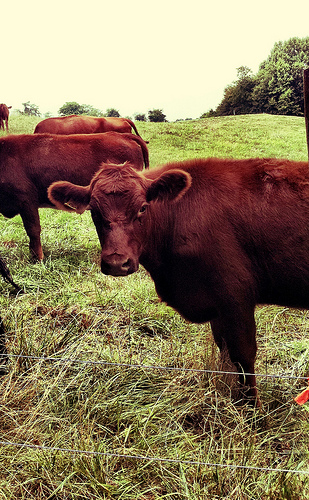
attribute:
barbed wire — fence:
[84, 357, 237, 384]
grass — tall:
[1, 110, 306, 496]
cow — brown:
[57, 150, 308, 400]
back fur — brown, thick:
[167, 156, 302, 168]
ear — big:
[45, 179, 92, 214]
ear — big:
[147, 168, 192, 203]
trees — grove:
[174, 26, 308, 140]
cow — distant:
[45, 111, 154, 145]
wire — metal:
[1, 350, 307, 386]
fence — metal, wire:
[0, 335, 307, 488]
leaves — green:
[255, 42, 305, 124]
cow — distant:
[0, 100, 13, 132]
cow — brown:
[47, 158, 303, 429]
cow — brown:
[2, 132, 150, 265]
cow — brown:
[36, 115, 147, 143]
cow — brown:
[0, 100, 14, 130]